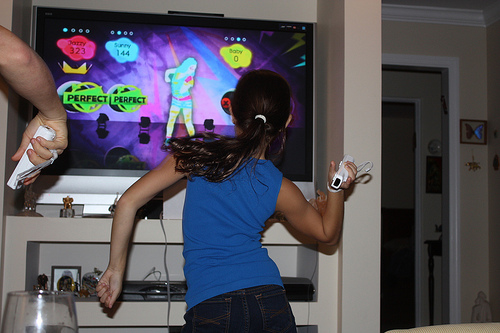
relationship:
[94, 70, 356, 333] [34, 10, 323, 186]
girl playing video game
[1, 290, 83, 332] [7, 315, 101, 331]
glass on table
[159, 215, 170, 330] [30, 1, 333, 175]
wire hanging down from video game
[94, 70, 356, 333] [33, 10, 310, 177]
girl playing a game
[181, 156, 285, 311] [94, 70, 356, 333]
shirt on girl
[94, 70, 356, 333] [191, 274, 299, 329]
girl wearing jeans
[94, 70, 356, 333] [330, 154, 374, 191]
girl holding control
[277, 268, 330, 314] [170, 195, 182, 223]
console has portion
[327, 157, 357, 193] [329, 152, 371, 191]
hand holding control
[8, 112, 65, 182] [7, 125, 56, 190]
hand holding controller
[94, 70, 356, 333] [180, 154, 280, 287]
girl wearing shirt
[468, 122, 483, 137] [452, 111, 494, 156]
butterfly in frame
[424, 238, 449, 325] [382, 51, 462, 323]
table through door way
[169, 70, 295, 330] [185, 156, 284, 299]
girl wearing shirt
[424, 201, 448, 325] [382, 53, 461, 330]
table between door way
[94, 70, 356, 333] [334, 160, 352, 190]
girl holding controller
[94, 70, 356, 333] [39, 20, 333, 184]
girl facing tv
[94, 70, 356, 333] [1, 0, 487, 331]
girl in house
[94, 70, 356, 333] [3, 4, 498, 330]
girl inside room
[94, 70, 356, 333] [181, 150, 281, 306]
girl wearing shirt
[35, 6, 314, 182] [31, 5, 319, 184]
game on tv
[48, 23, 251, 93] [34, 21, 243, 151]
scores on game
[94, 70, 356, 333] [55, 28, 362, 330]
girl enjoying recreation